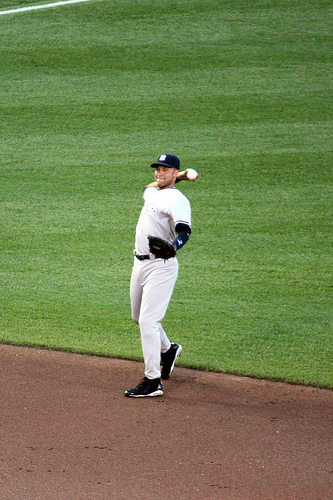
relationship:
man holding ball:
[124, 153, 198, 399] [183, 166, 198, 183]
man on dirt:
[124, 153, 198, 399] [0, 343, 330, 499]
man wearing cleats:
[124, 153, 198, 399] [124, 343, 182, 398]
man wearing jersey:
[124, 153, 198, 399] [126, 182, 213, 257]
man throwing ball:
[124, 153, 198, 399] [185, 168, 202, 186]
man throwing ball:
[124, 153, 198, 399] [181, 161, 200, 183]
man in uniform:
[124, 153, 198, 399] [127, 151, 197, 398]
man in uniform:
[124, 153, 198, 399] [128, 184, 193, 382]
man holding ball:
[124, 153, 198, 399] [186, 168, 197, 179]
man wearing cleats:
[85, 139, 234, 465] [122, 339, 185, 398]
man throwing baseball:
[124, 153, 198, 399] [186, 169, 196, 180]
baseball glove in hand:
[147, 235, 177, 260] [148, 236, 178, 259]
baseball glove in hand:
[147, 235, 177, 260] [144, 234, 177, 260]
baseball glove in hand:
[88, 130, 204, 246] [144, 234, 177, 260]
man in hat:
[124, 153, 198, 399] [146, 148, 184, 169]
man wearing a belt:
[124, 153, 198, 399] [135, 247, 168, 263]